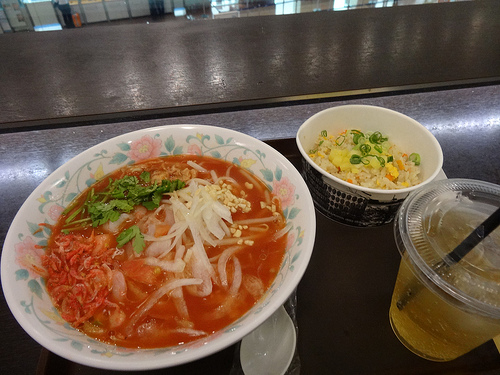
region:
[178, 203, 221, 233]
Onions on a plate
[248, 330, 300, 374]
spoon on the table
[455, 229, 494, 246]
A straw in juice cup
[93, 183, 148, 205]
coriander in the soup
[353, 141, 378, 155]
green pepper in the bowl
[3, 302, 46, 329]
a plate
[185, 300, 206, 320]
Red soup on a plate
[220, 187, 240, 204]
pieces of cheese on a plate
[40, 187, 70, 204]
flowers on a plate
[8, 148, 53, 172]
a table with a meal on it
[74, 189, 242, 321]
Soup in the bowl.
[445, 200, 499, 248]
A black straw in the cup.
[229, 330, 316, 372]
A spoon in a plastic wrapper.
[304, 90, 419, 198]
a cup of rice.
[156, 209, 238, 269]
Onions in the soup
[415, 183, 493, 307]
The cup has a lid on top.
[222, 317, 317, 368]
Spoon under the bowl of soup.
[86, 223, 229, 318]
The soup has a red sauce.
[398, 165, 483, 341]
A cup sitting o the table.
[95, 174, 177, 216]
Green leaves in the soup.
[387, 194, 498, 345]
plastic cup with a gold liquid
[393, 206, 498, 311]
black plastic straw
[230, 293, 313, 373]
white plastic spoon wrapped in plastic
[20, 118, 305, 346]
soup in a flooural ceramic bowl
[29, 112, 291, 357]
white bowl with a floral design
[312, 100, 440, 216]
small cardboard container with white rice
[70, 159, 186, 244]
green garnish on top of soup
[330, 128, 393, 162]
green scallions on top of rice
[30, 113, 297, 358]
orange soup in large bowl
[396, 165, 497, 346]
ginger ale in a plastic cup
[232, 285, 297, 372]
plastic white spoon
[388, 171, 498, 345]
clear plastic cup with ginger ale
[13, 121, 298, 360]
red soup with green garnish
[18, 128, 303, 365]
whie ceramic bowl with a flower print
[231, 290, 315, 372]
plastic spoon covered with plastic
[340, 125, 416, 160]
green scallions on top of white rice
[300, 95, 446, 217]
rice in a small cardboard bowl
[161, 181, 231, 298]
onion slices on top of soup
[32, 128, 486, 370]
lunch on brown tray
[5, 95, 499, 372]
Food sitting on plastic tray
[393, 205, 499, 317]
Black straw in plastic cup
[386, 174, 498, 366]
Plastic cup holding liquid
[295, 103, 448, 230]
Cup of ramen with vegetables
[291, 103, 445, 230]
Paper cup holding soup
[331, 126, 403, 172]
Green onions and corn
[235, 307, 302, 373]
Ladle of white plastic spoon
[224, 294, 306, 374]
Spoon in clear plastic package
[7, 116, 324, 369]
Floral plate holding meal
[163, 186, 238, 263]
Sliced white onions